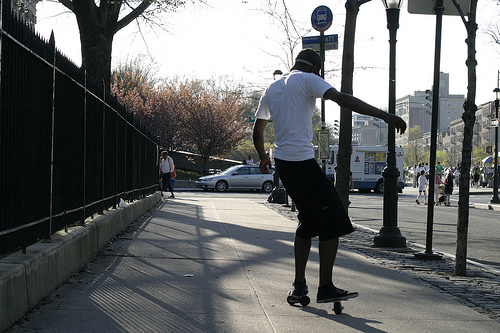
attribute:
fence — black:
[1, 3, 166, 270]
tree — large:
[53, 0, 192, 105]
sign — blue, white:
[305, 3, 334, 36]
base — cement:
[6, 185, 166, 320]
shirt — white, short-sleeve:
[256, 72, 335, 159]